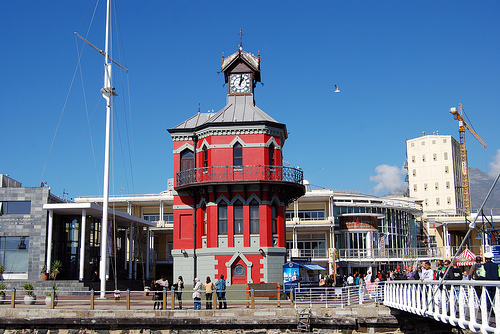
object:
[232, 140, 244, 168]
windows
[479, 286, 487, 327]
post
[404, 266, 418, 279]
people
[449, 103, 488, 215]
crane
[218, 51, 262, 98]
roof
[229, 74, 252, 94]
clock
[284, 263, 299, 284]
sign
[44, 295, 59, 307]
pot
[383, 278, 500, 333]
bridge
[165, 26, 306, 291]
building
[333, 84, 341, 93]
bird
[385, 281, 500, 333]
fence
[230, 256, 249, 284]
door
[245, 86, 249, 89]
numbers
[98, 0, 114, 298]
pole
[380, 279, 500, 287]
railing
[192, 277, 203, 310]
tourists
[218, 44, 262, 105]
top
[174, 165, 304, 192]
balcony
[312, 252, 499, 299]
crowd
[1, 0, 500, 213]
air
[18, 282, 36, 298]
plants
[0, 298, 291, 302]
line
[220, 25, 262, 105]
steeple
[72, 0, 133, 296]
sail